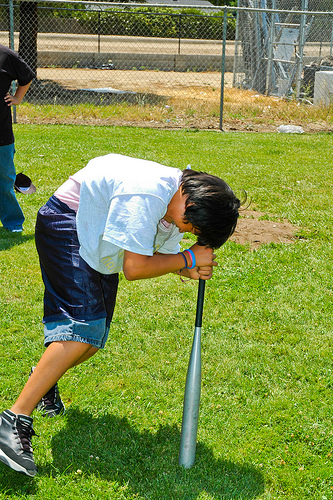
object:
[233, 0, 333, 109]
storage area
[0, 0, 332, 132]
fence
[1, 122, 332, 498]
ball park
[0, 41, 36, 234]
person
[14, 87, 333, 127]
ground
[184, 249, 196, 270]
bracelets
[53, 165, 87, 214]
undershirt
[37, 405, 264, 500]
shadow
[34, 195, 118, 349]
short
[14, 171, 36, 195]
hat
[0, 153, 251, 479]
boy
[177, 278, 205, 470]
baseball bat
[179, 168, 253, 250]
hair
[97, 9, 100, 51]
pole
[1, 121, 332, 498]
grass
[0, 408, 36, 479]
shoes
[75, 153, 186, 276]
shirt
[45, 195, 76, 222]
waist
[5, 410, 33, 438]
socks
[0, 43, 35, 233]
witness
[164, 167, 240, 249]
head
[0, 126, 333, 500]
field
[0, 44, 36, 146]
shirt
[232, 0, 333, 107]
area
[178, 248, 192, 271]
wrist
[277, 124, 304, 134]
patch